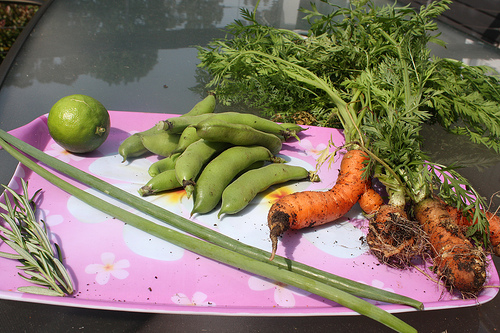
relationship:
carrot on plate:
[277, 141, 365, 240] [6, 107, 499, 325]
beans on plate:
[130, 95, 312, 212] [6, 107, 499, 325]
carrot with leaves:
[277, 141, 365, 240] [222, 25, 365, 134]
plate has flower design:
[6, 107, 499, 325] [78, 147, 373, 265]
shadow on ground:
[29, 7, 499, 78] [0, 6, 498, 207]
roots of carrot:
[258, 225, 285, 258] [277, 141, 365, 240]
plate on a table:
[6, 107, 499, 325] [2, 0, 499, 332]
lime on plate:
[43, 94, 111, 154] [6, 107, 499, 325]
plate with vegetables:
[6, 107, 499, 325] [125, 36, 497, 281]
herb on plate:
[2, 176, 73, 298] [6, 107, 499, 325]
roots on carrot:
[258, 225, 285, 258] [277, 141, 365, 240]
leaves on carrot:
[222, 25, 365, 134] [277, 141, 365, 240]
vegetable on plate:
[6, 127, 424, 332] [6, 107, 499, 325]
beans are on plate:
[130, 95, 312, 212] [6, 107, 499, 325]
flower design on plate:
[78, 147, 373, 265] [6, 107, 499, 325]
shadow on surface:
[0, 0, 225, 89] [5, 4, 495, 202]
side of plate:
[1, 109, 52, 229] [6, 107, 499, 325]